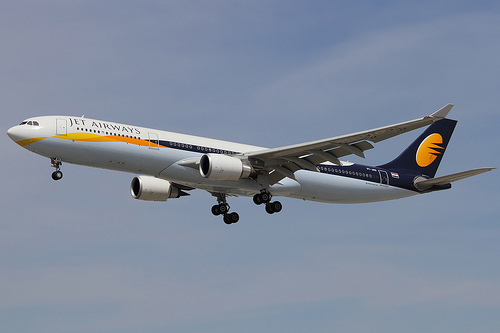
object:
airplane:
[6, 102, 496, 224]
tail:
[374, 118, 496, 203]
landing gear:
[208, 191, 240, 224]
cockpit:
[6, 115, 48, 149]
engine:
[199, 153, 269, 181]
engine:
[129, 175, 190, 203]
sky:
[3, 2, 497, 330]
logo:
[415, 133, 445, 169]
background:
[407, 118, 458, 179]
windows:
[188, 145, 192, 148]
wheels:
[227, 211, 239, 223]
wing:
[236, 103, 454, 185]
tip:
[5, 124, 18, 139]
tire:
[217, 204, 227, 214]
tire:
[259, 192, 272, 202]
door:
[56, 118, 67, 135]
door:
[378, 170, 389, 185]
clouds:
[3, 2, 498, 327]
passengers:
[16, 86, 454, 218]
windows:
[32, 121, 39, 127]